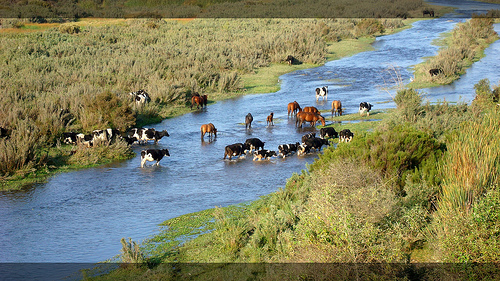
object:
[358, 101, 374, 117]
animal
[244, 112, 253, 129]
animal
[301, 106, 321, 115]
horse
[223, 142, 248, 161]
animal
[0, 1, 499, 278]
water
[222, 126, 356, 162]
group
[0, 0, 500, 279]
river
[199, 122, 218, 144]
horse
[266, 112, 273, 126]
horse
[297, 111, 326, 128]
horse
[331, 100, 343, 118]
horse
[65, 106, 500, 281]
grass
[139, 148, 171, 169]
animal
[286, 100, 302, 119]
horses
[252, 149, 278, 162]
cows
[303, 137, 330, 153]
cows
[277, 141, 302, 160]
cows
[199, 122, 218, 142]
animal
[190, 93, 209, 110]
animal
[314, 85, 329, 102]
animal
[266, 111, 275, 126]
animal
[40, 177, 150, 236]
water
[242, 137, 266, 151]
cow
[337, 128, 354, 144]
cow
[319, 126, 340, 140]
cow